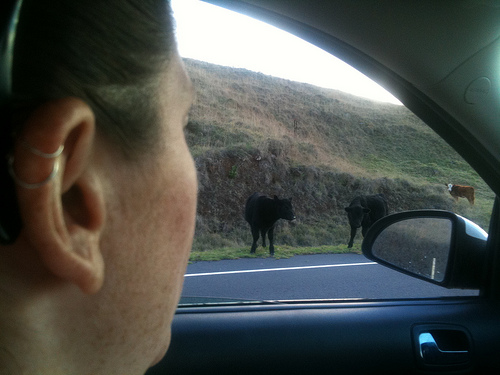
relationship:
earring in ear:
[15, 132, 67, 160] [6, 96, 112, 300]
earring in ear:
[6, 154, 62, 192] [6, 96, 112, 300]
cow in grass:
[444, 178, 480, 211] [178, 55, 498, 264]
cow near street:
[338, 188, 386, 257] [172, 243, 481, 305]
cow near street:
[239, 187, 299, 261] [172, 243, 481, 305]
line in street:
[189, 257, 378, 279] [172, 243, 481, 305]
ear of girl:
[6, 96, 112, 300] [1, 0, 207, 374]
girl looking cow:
[1, 0, 207, 374] [444, 178, 480, 211]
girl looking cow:
[1, 0, 207, 374] [338, 188, 386, 257]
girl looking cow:
[1, 0, 207, 374] [239, 187, 299, 261]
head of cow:
[443, 181, 455, 195] [444, 178, 480, 211]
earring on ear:
[15, 132, 67, 160] [6, 96, 112, 300]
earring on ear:
[6, 154, 62, 192] [6, 96, 112, 300]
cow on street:
[444, 178, 480, 211] [172, 243, 481, 305]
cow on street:
[338, 188, 386, 257] [172, 243, 481, 305]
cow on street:
[239, 187, 299, 261] [172, 243, 481, 305]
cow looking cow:
[239, 187, 299, 261] [338, 188, 386, 257]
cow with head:
[444, 178, 480, 211] [443, 181, 455, 195]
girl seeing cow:
[1, 0, 207, 374] [444, 178, 480, 211]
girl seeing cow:
[1, 0, 207, 374] [338, 188, 386, 257]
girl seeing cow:
[1, 0, 207, 374] [239, 187, 299, 261]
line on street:
[189, 257, 378, 279] [172, 243, 481, 305]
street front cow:
[172, 243, 481, 305] [444, 178, 480, 211]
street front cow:
[172, 243, 481, 305] [338, 188, 386, 257]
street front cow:
[172, 243, 481, 305] [239, 187, 299, 261]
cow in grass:
[338, 188, 386, 257] [178, 55, 498, 264]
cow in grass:
[239, 187, 299, 261] [178, 55, 498, 264]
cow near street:
[444, 178, 480, 211] [172, 243, 481, 305]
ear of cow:
[269, 190, 278, 203] [239, 187, 299, 261]